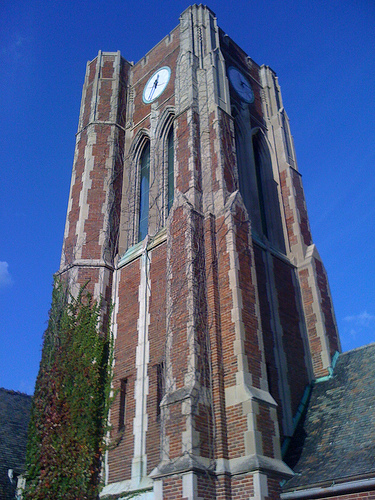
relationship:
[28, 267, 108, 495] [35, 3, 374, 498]
vines on building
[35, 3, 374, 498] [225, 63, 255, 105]
building with a clock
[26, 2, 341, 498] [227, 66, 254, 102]
building with clock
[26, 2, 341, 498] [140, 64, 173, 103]
building with clock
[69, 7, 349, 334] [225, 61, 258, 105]
building with clock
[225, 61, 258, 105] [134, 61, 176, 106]
clock with clock